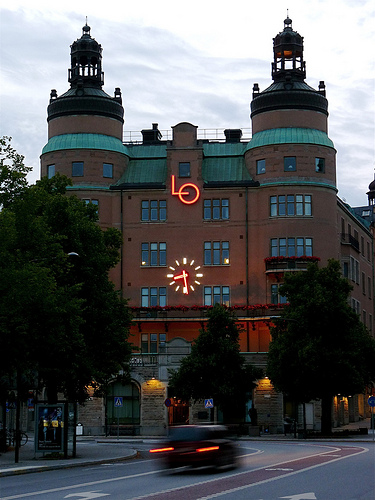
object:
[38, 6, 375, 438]
building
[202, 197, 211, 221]
window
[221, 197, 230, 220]
window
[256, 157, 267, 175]
window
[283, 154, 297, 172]
window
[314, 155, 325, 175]
window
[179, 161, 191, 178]
window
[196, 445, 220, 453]
light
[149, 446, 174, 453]
light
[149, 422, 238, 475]
car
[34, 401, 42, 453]
border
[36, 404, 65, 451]
poster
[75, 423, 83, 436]
trash can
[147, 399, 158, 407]
bricks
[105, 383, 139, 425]
drapes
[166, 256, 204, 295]
clock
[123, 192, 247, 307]
wall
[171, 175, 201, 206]
logo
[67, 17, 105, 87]
steeple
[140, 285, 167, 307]
window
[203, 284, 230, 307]
window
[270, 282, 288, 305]
window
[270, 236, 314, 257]
window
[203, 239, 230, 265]
window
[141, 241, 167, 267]
window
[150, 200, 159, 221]
window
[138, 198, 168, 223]
window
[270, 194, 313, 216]
window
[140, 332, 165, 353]
window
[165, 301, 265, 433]
tree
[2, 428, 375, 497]
road